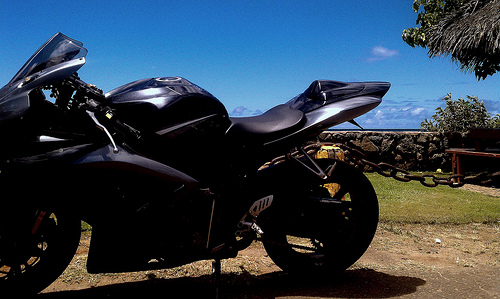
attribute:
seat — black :
[224, 103, 305, 140]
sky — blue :
[160, 12, 303, 94]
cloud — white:
[373, 46, 397, 58]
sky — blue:
[4, 0, 497, 97]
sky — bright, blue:
[117, 6, 419, 75]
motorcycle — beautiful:
[0, 26, 423, 276]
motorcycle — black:
[1, 24, 373, 279]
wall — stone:
[327, 125, 447, 171]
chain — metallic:
[352, 140, 499, 196]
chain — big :
[354, 135, 431, 187]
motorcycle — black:
[1, 44, 464, 279]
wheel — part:
[333, 217, 369, 249]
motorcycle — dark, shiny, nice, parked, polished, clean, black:
[4, 31, 397, 296]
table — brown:
[448, 143, 496, 178]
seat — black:
[149, 77, 363, 170]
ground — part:
[443, 230, 478, 257]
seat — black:
[231, 103, 303, 140]